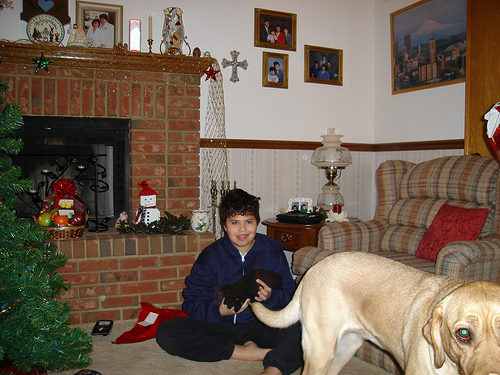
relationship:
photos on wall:
[251, 10, 351, 95] [201, 10, 370, 178]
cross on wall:
[215, 48, 248, 85] [201, 10, 370, 178]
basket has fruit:
[47, 224, 95, 240] [40, 200, 90, 224]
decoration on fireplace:
[137, 170, 166, 237] [3, 42, 211, 331]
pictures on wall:
[251, 5, 299, 94] [201, 10, 370, 178]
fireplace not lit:
[3, 42, 211, 331] [32, 156, 118, 211]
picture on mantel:
[71, 2, 128, 52] [10, 43, 213, 69]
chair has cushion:
[380, 161, 498, 273] [428, 202, 471, 262]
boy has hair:
[158, 186, 301, 373] [224, 185, 267, 219]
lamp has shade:
[321, 120, 349, 217] [312, 135, 354, 167]